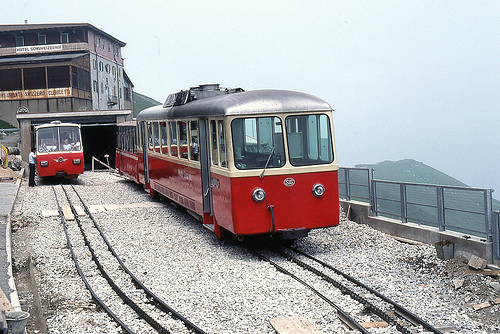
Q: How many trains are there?
A: 2.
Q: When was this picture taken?
A: Daytime.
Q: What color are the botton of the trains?
A: Red.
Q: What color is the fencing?
A: Silver.